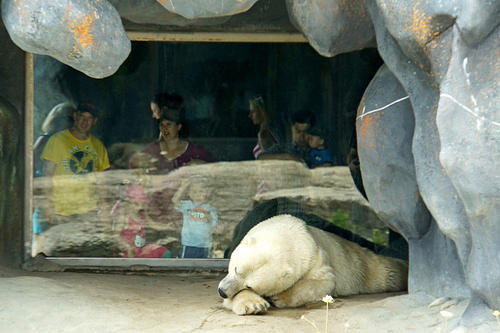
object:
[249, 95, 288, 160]
people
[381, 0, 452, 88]
yellow paint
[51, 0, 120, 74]
yellow paint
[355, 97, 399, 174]
yellow paint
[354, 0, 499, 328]
rocks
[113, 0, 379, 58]
rocks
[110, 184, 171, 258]
child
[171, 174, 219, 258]
child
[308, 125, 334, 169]
child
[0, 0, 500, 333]
cave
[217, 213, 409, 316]
bear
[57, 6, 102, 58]
spots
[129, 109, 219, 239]
person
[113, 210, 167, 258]
dress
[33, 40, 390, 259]
window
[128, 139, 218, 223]
shirt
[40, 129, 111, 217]
shirt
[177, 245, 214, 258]
pant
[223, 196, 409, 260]
blanket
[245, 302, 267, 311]
claws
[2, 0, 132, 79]
rock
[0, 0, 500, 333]
zoo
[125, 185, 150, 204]
cap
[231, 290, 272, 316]
paw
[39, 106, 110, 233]
man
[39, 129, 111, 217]
t-shirt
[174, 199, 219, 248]
baby tee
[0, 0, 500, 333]
cage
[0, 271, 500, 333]
floor